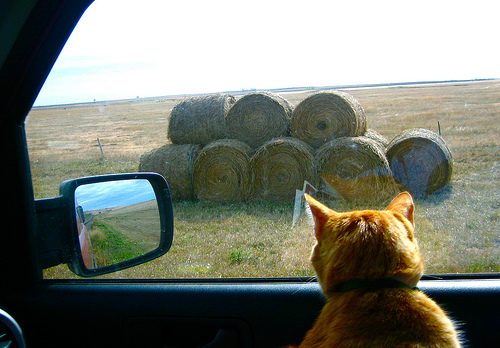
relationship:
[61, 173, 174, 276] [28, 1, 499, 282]
mirror out window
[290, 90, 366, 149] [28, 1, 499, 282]
bale out window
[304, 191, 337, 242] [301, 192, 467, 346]
ear of cat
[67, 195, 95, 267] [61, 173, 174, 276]
reflection in mirror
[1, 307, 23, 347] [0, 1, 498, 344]
vent in car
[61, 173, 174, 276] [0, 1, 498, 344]
mirror on car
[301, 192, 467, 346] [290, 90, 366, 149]
cat looking at bale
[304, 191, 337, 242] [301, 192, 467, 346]
ear on cat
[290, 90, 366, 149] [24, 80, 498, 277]
bale in field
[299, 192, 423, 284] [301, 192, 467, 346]
head of cat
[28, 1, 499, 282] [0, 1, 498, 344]
window in car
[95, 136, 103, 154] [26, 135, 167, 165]
fence on post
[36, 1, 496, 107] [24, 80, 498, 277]
sky above field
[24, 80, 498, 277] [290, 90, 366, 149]
field under bale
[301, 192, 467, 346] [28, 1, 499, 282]
cat looking out window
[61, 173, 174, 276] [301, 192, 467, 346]
mirror by cat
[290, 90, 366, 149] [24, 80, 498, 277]
bale on field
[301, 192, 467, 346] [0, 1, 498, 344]
cat in car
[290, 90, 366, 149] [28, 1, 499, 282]
bale outside window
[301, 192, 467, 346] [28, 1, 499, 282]
cat in window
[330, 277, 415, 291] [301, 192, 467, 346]
collar on cat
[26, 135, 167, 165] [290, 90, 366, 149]
post behind bale